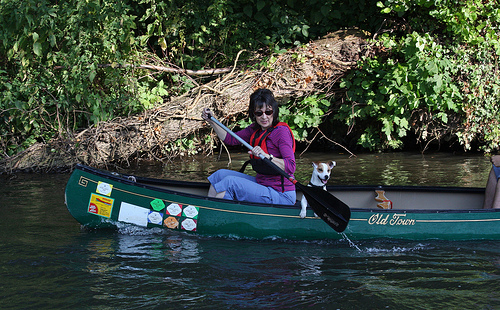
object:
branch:
[360, 51, 497, 148]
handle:
[205, 108, 266, 160]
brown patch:
[318, 163, 322, 169]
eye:
[318, 169, 323, 172]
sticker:
[147, 198, 200, 232]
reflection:
[88, 235, 324, 291]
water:
[7, 219, 77, 272]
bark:
[250, 65, 311, 88]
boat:
[64, 156, 500, 243]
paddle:
[206, 108, 351, 233]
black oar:
[300, 185, 351, 233]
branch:
[36, 55, 240, 100]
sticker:
[87, 192, 115, 218]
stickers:
[117, 201, 150, 227]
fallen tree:
[0, 0, 499, 173]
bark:
[95, 124, 131, 154]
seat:
[374, 189, 390, 209]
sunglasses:
[253, 110, 273, 116]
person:
[201, 88, 296, 206]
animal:
[299, 160, 337, 218]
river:
[0, 149, 499, 308]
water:
[280, 262, 497, 309]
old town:
[367, 213, 415, 226]